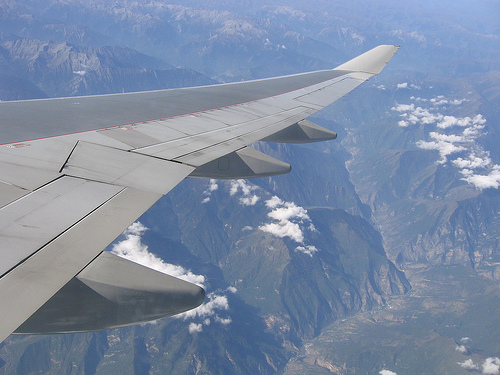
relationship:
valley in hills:
[237, 248, 423, 372] [5, 117, 413, 371]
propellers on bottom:
[16, 238, 227, 342] [189, 146, 292, 179]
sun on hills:
[17, 25, 115, 81] [5, 117, 413, 371]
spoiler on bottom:
[52, 135, 199, 205] [189, 146, 292, 179]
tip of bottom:
[331, 44, 401, 78] [189, 146, 292, 179]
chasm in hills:
[334, 135, 419, 294] [5, 117, 413, 371]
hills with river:
[5, 117, 413, 371] [322, 135, 432, 302]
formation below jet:
[391, 86, 497, 209] [7, 33, 411, 373]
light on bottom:
[8, 132, 38, 158] [189, 146, 292, 179]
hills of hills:
[5, 117, 413, 371] [5, 117, 413, 371]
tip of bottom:
[331, 32, 401, 97] [189, 146, 292, 179]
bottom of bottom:
[47, 123, 364, 348] [189, 146, 292, 179]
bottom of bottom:
[194, 146, 315, 190] [189, 146, 292, 179]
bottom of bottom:
[270, 115, 337, 145] [189, 146, 292, 179]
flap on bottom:
[63, 135, 203, 209] [189, 146, 292, 179]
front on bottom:
[1, 77, 147, 146] [189, 146, 292, 179]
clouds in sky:
[398, 72, 497, 206] [8, 1, 498, 369]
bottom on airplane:
[189, 146, 292, 179] [2, 42, 401, 342]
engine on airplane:
[259, 118, 339, 145] [2, 42, 401, 342]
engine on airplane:
[189, 146, 291, 179] [2, 42, 401, 342]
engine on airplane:
[10, 249, 205, 333] [2, 42, 401, 342]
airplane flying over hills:
[2, 43, 400, 343] [5, 117, 413, 371]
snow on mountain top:
[202, 178, 320, 258] [2, 0, 497, 371]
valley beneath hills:
[237, 248, 423, 372] [5, 117, 413, 371]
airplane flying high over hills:
[2, 43, 400, 343] [5, 117, 413, 371]